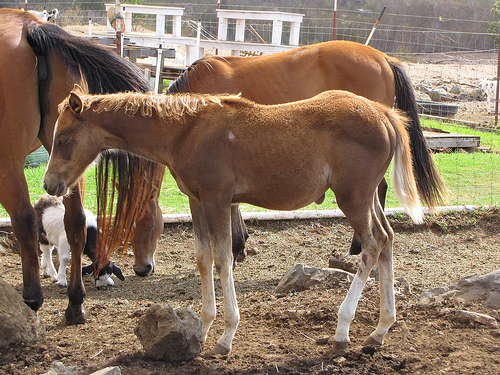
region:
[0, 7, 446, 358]
Three horses standing around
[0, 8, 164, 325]
The horse is an adult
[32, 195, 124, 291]
A black and white goat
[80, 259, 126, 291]
Goat is sniffing the ground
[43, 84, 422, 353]
The horse is young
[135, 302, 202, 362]
Gray rock near the horse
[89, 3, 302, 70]
White building in background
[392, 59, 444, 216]
Tail is dark brown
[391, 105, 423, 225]
Tail is brown and white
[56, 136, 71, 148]
Horse is squinting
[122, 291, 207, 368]
Large gray rock near horse.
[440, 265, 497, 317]
Large gray rock on ground.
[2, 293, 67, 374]
Gray rock on ground near horse.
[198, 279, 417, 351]
Bottom of horse's legs are white.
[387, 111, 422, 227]
Horse has white and brown tail.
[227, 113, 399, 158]
Horse has brown back.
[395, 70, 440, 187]
Horse has black tail.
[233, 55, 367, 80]
Horse has brown back.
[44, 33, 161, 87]
Horse has black tail.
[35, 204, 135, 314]
Black and white animal standing on ground.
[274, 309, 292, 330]
Small patch of brown dirt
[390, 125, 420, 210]
White and brown tail of horse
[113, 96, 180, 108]
Gold hair of the horse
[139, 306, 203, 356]
Medium-sized rock in the dirt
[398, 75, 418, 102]
Black tail of the horse in the back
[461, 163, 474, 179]
Small patch of green grass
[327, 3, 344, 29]
Red and white pole in the distance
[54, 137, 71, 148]
Left eye of the first horse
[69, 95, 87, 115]
Left ear of the first horse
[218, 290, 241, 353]
Front left leg of horse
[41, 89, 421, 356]
A small brown horse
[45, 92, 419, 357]
A young brown horse with white legs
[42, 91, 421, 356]
A small young light tan horse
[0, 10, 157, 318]
The back end of a large horse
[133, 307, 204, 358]
A small gray rock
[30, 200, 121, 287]
A young goat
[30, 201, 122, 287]
A small goat with black and white fur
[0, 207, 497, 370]
A large area of soft dirt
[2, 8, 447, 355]
A grouping of several horses and a goat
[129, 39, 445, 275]
A young horse with its nose to the ground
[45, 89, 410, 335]
this is a horse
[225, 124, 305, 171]
the horse is brown in color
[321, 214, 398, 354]
these are the legs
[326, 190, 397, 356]
the legs are long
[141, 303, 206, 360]
this is a stone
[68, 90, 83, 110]
this is the ear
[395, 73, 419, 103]
this is the tail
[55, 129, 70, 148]
the eye is closed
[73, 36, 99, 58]
the tail is black in color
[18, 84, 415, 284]
the horse is small in size